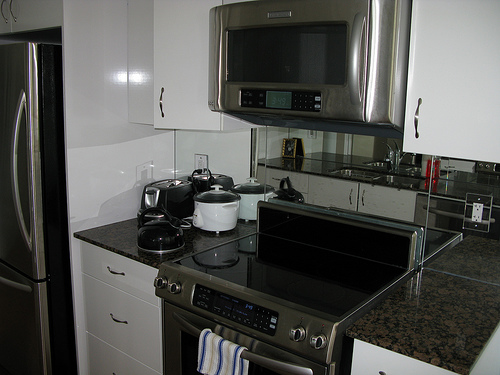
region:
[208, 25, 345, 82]
microwave on the stove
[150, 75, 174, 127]
handle of the cabinet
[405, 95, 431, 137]
handle of the cabinet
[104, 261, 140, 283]
handle of the cabinet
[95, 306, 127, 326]
handle of the cabinet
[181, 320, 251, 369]
towel on the rack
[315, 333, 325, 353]
knob on the oven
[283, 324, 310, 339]
knob on the oven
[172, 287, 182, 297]
knob on the oven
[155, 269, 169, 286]
knob on the oven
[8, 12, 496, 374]
a very clean looking kitchen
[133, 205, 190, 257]
pot for boiling water is on the counter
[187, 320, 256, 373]
dishtowel hanging in front of the oven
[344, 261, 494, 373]
countertop is patterned marble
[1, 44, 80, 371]
refrigerator looks pretty huge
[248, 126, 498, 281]
the wall is mirrored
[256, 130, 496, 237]
the rest of the kitchen is reflected in the mirrored wall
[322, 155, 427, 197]
the double sink on the other side of the kitchen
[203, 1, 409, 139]
microwave mounter over the stove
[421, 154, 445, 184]
the dish soap is the only color in the room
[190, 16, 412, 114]
a silver kitchen microwave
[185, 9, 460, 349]
a microwave above the stove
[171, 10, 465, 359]
a microwave above the oven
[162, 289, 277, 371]
a towel on the oven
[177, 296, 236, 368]
a towel hanging on an oven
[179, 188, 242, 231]
a small crock pot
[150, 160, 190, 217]
a black toaster on the counter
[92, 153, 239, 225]
a toaster on the counter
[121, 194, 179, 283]
a teapot on the counter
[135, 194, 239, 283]
a teapot that is black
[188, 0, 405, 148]
stainless steel microwave in between cabinets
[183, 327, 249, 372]
blue and beige striped towel hanging on oven door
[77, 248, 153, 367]
white cabinets with silver handle pulls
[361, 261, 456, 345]
brown and black granite counter top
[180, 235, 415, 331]
top of an electric stove top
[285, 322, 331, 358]
chrome knobs on stainless steel stove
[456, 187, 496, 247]
electrical outlet mounted in the wall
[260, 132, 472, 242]
reflection of the sink in the mirror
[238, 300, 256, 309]
small illuminate clock on the stove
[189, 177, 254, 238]
white crock pot with glass lid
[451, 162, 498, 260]
a power outlet on a wall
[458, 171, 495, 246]
a white power outlet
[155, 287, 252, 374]
a white and blue dish towel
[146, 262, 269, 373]
a dish towel on a oven door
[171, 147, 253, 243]
a white slow cooker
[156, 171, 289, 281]
a slow cooker on a counter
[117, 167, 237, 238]
a black toaster oven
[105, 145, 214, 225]
a toaster oven on the counter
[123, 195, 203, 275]
a black tea kettle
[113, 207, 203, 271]
a tea kettle on a counter